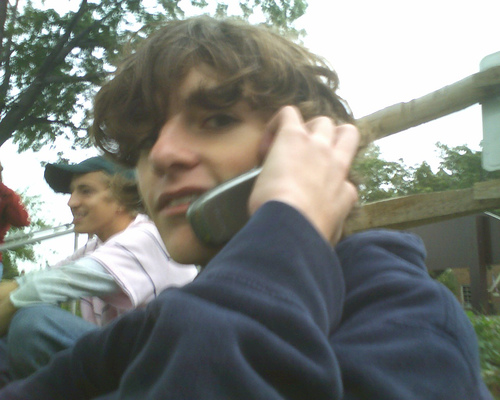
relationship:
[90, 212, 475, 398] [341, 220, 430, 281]
sweatshirt has hood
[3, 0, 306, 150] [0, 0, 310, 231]
green leaves on tree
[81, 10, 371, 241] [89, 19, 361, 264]
hair on head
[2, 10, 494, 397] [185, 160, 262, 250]
boy on phone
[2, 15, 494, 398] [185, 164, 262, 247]
boy holding mobile phone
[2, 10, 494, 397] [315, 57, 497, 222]
boy seated near a fence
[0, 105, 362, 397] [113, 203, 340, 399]
arm with sleeve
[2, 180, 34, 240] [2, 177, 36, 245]
arm with red sleeve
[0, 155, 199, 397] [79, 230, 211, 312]
boy wearing a shirt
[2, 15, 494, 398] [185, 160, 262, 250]
boy talking on phone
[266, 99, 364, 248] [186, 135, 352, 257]
hand holding phone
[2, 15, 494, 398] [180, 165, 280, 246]
boy talks on a phone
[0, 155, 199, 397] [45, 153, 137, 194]
boy wears cap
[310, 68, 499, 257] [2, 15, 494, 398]
wood fence behind boy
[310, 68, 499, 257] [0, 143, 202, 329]
wood fence behind boy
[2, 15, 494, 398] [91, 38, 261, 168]
boy has bangs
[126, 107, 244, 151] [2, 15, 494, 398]
eyes of boy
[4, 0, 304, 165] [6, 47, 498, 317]
tree on side of a fence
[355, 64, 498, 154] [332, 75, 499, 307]
post of fence